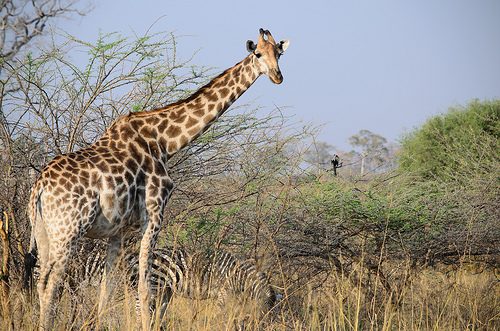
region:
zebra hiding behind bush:
[151, 243, 286, 328]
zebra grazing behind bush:
[131, 246, 281, 328]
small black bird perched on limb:
[328, 152, 345, 179]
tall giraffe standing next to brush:
[20, 8, 294, 330]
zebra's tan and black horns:
[252, 26, 277, 43]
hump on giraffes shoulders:
[103, 108, 155, 145]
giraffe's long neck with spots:
[146, 57, 254, 152]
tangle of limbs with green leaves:
[243, 180, 497, 325]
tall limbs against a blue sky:
[3, 3, 218, 198]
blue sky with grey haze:
[4, 1, 497, 147]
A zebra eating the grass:
[125, 248, 273, 327]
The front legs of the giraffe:
[100, 228, 158, 330]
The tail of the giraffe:
[22, 189, 40, 269]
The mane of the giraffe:
[131, 64, 238, 117]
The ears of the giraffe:
[245, 40, 289, 52]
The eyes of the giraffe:
[254, 50, 288, 58]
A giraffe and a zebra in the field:
[23, 29, 290, 329]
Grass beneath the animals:
[6, 294, 498, 329]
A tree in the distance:
[351, 133, 385, 173]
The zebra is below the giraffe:
[128, 252, 280, 329]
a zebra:
[160, 250, 185, 293]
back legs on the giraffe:
[40, 253, 65, 326]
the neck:
[188, 87, 229, 117]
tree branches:
[306, 215, 373, 267]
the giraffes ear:
[240, 38, 255, 50]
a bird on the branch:
[321, 151, 343, 176]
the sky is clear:
[306, 27, 409, 79]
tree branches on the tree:
[8, 18, 40, 45]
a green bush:
[404, 133, 439, 158]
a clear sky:
[306, 17, 440, 94]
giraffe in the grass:
[14, 17, 299, 329]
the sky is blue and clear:
[299, 17, 449, 88]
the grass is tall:
[255, 243, 445, 330]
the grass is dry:
[292, 251, 485, 322]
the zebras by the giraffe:
[119, 237, 280, 326]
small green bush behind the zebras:
[251, 147, 451, 260]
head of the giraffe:
[233, 25, 293, 91]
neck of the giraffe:
[132, 47, 263, 169]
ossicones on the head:
[251, 25, 277, 40]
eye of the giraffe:
[250, 45, 266, 56]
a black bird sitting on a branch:
[329, 153, 339, 176]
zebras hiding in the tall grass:
[68, 243, 270, 327]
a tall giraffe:
[28, 27, 287, 329]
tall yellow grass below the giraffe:
[9, 241, 499, 329]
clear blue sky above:
[10, 3, 498, 172]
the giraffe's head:
[247, 28, 288, 83]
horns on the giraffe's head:
[257, 26, 270, 41]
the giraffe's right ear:
[245, 40, 257, 53]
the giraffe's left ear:
[277, 39, 286, 50]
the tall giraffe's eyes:
[256, 50, 281, 59]